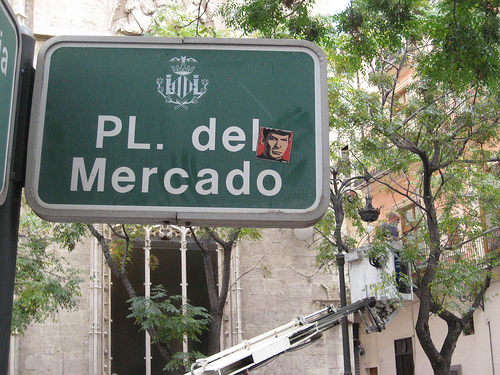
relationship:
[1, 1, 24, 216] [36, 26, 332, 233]
edge of sign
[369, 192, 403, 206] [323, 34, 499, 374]
brick on building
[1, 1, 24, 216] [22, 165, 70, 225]
corner of sign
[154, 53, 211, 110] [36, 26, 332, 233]
crest on sign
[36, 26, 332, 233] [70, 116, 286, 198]
sign with letters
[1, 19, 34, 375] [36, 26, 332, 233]
black holding sign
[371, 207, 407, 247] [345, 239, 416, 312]
man in basket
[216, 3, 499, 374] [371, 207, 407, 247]
trees obscuring man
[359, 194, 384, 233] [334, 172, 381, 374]
lamp on black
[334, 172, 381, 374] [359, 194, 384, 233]
black street lamp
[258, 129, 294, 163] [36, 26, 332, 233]
sticker on sign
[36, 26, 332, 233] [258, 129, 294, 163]
sign with sticker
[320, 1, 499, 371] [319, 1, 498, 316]
tree with leaves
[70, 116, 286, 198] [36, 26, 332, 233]
information on green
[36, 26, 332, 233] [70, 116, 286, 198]
sign in spanish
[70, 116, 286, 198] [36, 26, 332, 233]
spanish on sign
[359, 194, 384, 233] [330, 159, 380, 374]
light on pole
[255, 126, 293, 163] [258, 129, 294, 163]
image of spock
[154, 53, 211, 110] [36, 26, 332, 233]
emblem on sign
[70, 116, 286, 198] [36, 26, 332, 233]
white lettered green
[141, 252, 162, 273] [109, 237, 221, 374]
shape above door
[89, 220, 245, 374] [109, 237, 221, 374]
frame of doorway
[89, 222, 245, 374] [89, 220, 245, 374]
stone doorway frame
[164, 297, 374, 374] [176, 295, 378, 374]
white construction arm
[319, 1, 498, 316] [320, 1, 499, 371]
leaves on tree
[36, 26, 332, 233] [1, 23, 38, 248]
sign on pole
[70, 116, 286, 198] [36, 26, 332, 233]
white lettered sign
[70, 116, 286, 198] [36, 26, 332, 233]
white on sign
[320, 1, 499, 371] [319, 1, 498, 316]
tree has leaves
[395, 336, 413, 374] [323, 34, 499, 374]
window on building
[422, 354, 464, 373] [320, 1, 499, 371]
trunk of tree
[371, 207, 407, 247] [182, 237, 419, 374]
man in lift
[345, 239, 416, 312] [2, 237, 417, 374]
bucket of lift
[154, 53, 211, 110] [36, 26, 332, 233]
symbol on sign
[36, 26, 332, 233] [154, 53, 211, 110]
sign with symbol